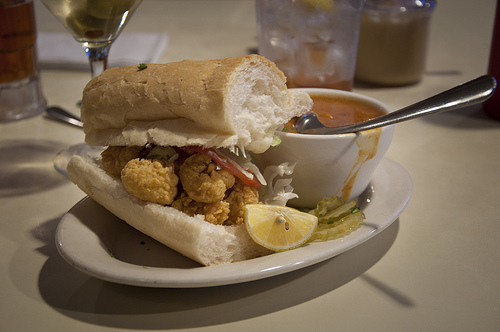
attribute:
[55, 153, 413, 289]
plate — white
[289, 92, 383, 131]
soup — orange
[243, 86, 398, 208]
bowl — white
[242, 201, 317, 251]
lemon — yellow, small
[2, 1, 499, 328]
table — white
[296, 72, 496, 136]
spoon — silver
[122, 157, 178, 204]
shrimp — fried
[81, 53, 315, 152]
bread — white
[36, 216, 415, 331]
shadow — black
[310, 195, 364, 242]
pickle — cut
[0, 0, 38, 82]
liquid — brown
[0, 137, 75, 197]
shadow — black